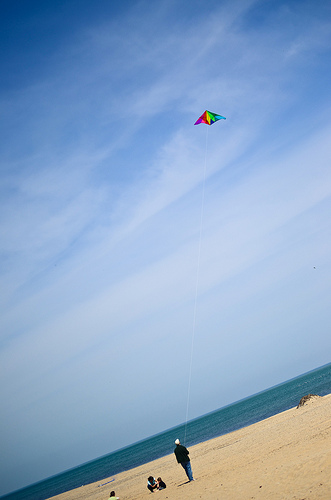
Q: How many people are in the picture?
A: One.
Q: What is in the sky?
A: A kite.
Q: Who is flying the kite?
A: A person.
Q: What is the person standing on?
A: Sand.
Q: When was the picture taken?
A: During the day.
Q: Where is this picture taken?
A: On the beach.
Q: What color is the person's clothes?
A: Black.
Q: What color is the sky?
A: Blue.